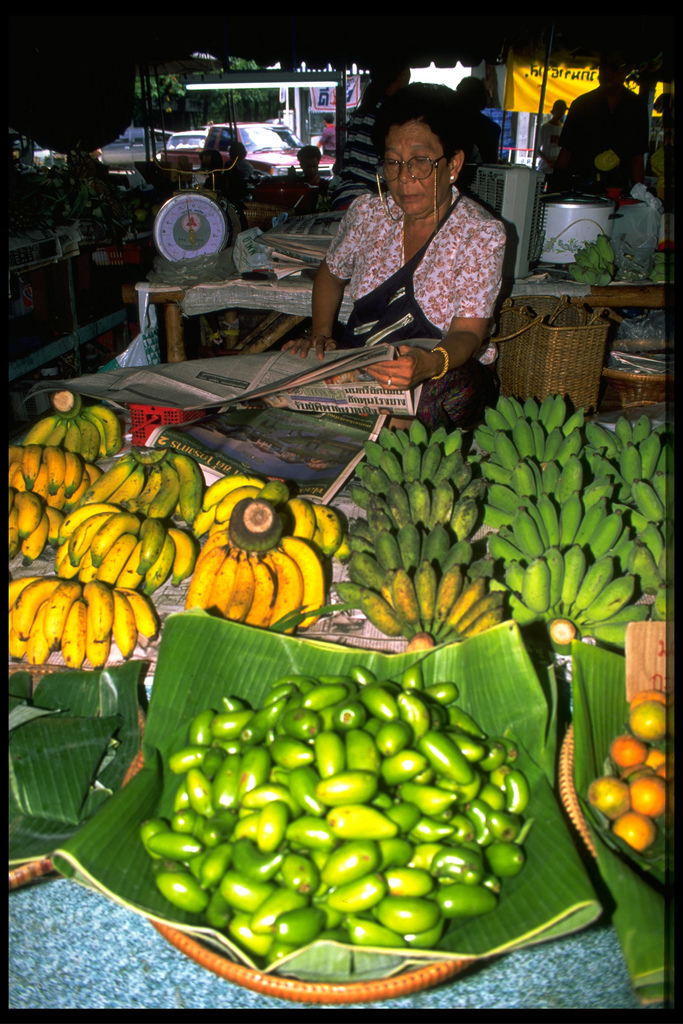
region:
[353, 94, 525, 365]
elderly woman behind the counter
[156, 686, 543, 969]
green fruit in bowl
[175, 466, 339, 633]
large bunch of yellow bananas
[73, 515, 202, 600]
large bunch of yellow bananas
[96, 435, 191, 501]
large bunch of yellow bananas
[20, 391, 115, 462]
large bunch of yellow bananas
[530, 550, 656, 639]
large bunch of green bananas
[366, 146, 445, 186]
glasses on the woman's face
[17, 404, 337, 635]
several bunches of yellow bananas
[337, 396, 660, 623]
several bunches of green bananas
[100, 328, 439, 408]
a newspaper in her hands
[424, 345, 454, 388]
an orange bracelet on her wrist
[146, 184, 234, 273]
a scale for measuring weight of fruit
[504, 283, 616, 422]
a brown wicker carrying basket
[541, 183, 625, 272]
a large white crock pot on the shelf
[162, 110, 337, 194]
a red parked truck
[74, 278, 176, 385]
a white plastic bag with green design on it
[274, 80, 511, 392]
woman wearing floral top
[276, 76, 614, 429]
brown wicker basket behind woman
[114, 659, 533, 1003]
small green peppers in basket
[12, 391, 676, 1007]
green bananas on table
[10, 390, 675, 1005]
yellow bananas on table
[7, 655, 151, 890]
green banana leaves in brown basket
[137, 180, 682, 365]
white crock pot on table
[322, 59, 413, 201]
person wearing blue and white striped top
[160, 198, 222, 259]
a large white scale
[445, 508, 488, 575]
a banana on display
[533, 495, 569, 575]
a banana on display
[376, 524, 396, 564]
a banana on display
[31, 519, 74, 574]
a banana on display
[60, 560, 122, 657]
a banana on display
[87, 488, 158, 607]
a banana on display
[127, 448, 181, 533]
a banana on display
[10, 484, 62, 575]
cluster of yellow bananas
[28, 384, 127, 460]
cluster of yellow bananas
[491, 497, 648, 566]
cluster of green bananas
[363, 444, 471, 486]
cluster of green bananas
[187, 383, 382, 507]
picture on front of newspaper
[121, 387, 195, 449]
red tag on newspaper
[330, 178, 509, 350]
pink and white floral shirt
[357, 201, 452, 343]
black apron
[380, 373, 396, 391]
silver ring on finger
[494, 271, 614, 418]
brown wicker basket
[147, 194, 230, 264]
scale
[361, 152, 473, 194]
glasses worn by older woman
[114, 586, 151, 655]
yellow and green bananas on table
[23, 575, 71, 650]
yellow and green bananas on table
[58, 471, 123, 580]
yellow and green bananas on table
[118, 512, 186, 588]
yellow and green bananas on table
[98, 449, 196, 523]
yellow and green bananas on table